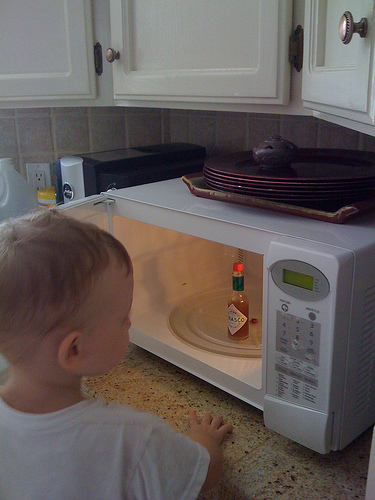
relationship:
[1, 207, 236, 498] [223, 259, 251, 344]
child looks at bottle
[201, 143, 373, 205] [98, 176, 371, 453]
plates stacked on microwave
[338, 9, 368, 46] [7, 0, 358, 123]
knob on cabinet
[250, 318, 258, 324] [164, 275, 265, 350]
crumb on plate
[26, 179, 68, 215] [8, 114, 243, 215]
container in corner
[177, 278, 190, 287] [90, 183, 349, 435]
food caked inside microwave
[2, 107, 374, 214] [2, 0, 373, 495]
backsplash in kitchen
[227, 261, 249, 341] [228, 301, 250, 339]
bottle of hot sauce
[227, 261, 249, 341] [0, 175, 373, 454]
bottle in microwave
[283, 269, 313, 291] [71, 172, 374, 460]
blank display on microwave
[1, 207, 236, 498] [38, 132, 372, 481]
child looking at microwave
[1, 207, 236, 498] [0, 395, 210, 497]
child wearing shirt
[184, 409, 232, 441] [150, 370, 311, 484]
hand on counter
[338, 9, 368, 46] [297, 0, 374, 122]
knob on cabinet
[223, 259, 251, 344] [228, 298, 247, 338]
bottle of sauce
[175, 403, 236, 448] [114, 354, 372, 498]
hand on counter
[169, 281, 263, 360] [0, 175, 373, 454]
plate in microwave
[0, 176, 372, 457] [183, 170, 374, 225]
tray on top of microwave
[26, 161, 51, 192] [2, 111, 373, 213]
outlet on wall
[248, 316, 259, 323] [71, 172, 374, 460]
crumb sitting in microwave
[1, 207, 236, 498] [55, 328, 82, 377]
child has ear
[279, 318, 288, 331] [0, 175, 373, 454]
number four on microwave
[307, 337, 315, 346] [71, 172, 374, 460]
nine on microwave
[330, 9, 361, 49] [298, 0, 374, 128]
knob on door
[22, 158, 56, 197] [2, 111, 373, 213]
outlet on wall